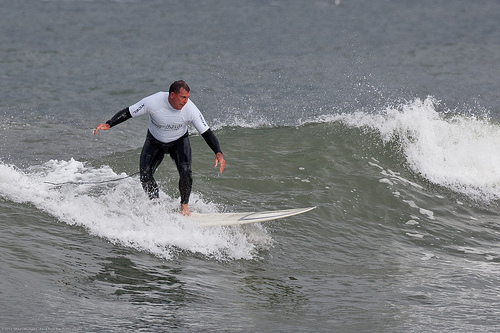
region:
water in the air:
[374, 78, 496, 146]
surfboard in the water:
[158, 191, 323, 234]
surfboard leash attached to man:
[43, 158, 144, 195]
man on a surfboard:
[61, 71, 332, 256]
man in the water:
[64, 53, 285, 260]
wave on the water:
[1, 93, 487, 261]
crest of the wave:
[83, 88, 492, 161]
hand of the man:
[201, 144, 239, 184]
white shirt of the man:
[118, 90, 211, 157]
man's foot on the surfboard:
[157, 189, 199, 226]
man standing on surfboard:
[91, 77, 315, 223]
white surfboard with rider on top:
[148, 203, 314, 225]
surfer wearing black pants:
[92, 80, 225, 220]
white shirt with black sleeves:
[102, 89, 220, 152]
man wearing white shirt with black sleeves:
[89, 81, 225, 216]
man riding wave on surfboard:
[3, 80, 497, 260]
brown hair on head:
[165, 80, 192, 109]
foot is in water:
[177, 200, 192, 218]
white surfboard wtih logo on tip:
[143, 208, 323, 226]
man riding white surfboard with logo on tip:
[86, 77, 314, 227]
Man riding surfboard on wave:
[86, 76, 318, 231]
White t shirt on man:
[125, 91, 210, 143]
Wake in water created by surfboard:
[1, 156, 268, 268]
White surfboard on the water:
[158, 205, 318, 232]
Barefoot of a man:
[166, 200, 196, 217]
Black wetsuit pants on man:
[119, 130, 199, 204]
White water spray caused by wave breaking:
[322, 93, 497, 198]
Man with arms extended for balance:
[78, 80, 233, 215]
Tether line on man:
[42, 166, 142, 191]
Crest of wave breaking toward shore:
[338, 99, 499, 228]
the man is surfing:
[97, 80, 309, 230]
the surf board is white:
[188, 205, 315, 232]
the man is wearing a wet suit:
[91, 82, 221, 216]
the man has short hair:
[168, 83, 190, 109]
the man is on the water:
[89, 80, 313, 222]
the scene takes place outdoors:
[1, 0, 498, 332]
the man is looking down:
[171, 84, 191, 108]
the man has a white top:
[130, 89, 210, 141]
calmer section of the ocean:
[1, 0, 498, 172]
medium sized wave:
[0, 93, 499, 332]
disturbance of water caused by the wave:
[0, 153, 277, 260]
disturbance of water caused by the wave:
[190, 82, 499, 204]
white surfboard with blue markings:
[176, 205, 318, 229]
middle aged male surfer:
[91, 78, 229, 219]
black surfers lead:
[42, 170, 139, 187]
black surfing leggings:
[137, 127, 192, 202]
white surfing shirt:
[126, 90, 206, 142]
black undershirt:
[106, 91, 223, 154]